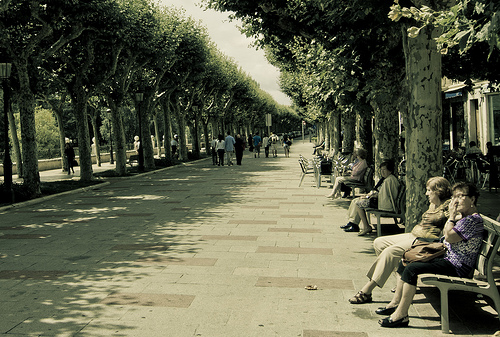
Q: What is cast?
A: Shadow.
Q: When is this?
A: Daytime.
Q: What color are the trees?
A: Green.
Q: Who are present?
A: People.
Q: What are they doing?
A: Sitting.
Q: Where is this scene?
A: In a pedestrian walkway.